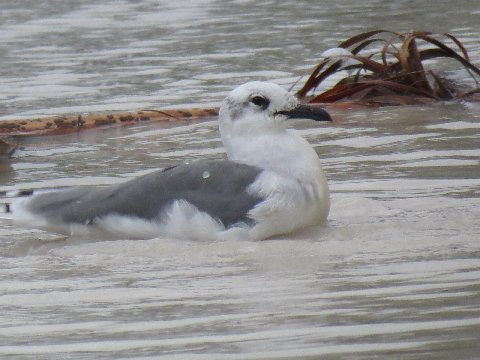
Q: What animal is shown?
A: Bird.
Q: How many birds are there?
A: One.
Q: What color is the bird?
A: White.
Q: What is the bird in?
A: Water.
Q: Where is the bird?
A: River.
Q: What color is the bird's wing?
A: Grey.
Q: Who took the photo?
A: Watcher.